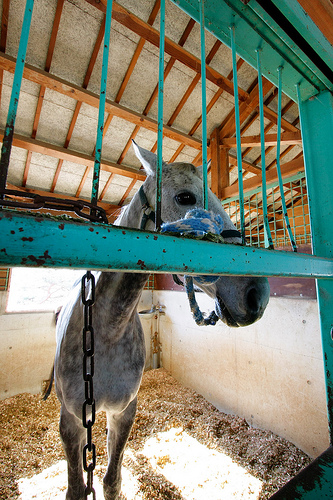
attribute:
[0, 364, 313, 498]
chips — wood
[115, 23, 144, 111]
rafter — wooden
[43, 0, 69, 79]
rafter — wooden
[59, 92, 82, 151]
rafter — wooden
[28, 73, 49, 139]
rafter — wooden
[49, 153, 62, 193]
rafter — wooden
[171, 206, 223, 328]
rope — blue, white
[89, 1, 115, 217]
bar — metal, aqua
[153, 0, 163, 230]
bar — metal, aqua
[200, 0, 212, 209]
bar — metal, aqua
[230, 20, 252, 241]
bar — metal, aqua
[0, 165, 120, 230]
chain — large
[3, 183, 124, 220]
chain — hanging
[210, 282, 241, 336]
mouth — horse's, closed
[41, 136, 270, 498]
horse — white, brown